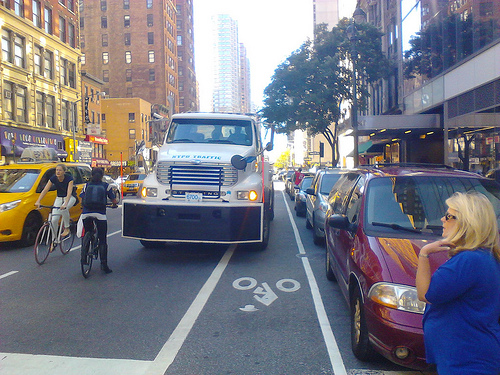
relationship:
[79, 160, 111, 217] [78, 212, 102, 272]
person riding a bicycle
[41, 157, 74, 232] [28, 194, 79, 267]
person riding a bicycle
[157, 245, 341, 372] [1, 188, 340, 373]
lines on street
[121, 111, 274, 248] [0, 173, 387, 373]
truck driving down a street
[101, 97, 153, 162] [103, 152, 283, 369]
orange building on left side of street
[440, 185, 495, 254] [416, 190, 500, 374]
hair of a lady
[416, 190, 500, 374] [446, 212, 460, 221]
lady wearing glasses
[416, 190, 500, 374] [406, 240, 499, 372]
lady wearing shirt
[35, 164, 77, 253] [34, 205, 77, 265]
person riding a bicycle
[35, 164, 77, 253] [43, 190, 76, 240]
person wearing white pants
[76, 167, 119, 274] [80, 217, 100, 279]
person riding a bicycle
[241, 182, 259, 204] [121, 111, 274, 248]
headlight on a truck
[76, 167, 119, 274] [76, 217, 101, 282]
person riding bicycle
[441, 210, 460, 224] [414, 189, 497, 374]
glasses worn by lady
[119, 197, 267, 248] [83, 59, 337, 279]
bumper on truck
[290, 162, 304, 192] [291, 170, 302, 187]
person with shirt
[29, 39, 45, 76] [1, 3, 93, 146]
window on yellow building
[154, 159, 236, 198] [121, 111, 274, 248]
grill of truck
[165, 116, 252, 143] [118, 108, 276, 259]
windshield of truck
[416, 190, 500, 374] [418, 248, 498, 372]
lady wearing shirt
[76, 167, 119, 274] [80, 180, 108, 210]
person wearing backpack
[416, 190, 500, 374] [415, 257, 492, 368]
lady wearing shirt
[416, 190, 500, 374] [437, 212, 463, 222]
lady wearing sunglasses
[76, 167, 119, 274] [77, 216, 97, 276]
person on bicycle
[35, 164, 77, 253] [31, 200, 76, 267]
person on bicycle